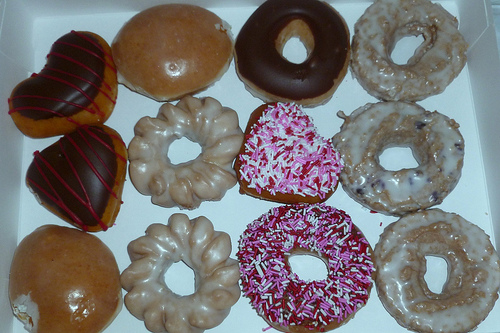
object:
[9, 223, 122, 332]
doughnut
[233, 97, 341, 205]
green leaves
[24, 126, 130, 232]
doughnut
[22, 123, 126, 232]
glaze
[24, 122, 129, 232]
drizzle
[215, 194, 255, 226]
table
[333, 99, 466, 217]
doughnut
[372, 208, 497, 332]
doughnut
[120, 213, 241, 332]
doughnut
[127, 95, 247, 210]
doughnut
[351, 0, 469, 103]
doughnut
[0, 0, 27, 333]
edge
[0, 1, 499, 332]
box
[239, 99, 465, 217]
doughnut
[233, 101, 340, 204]
doughnut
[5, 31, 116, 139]
glaze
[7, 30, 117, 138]
drizzle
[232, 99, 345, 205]
sprinkles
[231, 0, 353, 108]
chocolate